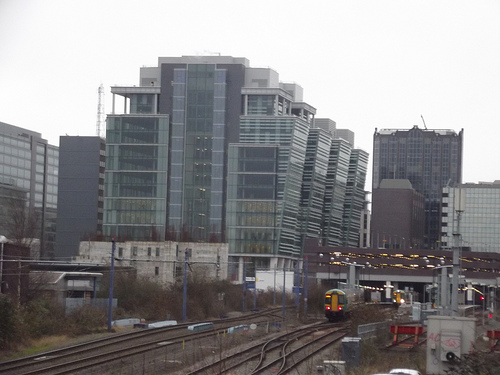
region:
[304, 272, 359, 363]
Yellow train on tracks.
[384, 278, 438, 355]
Yellow train on tracks.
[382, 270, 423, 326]
Headlights are on on the train.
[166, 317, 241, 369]
Many train tracks beside each other.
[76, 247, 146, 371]
Tall post in ground.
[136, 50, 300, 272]
Large building near tracks.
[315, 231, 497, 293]
Parking garage near trains.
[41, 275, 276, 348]
Brown trees near tracks.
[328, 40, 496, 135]
No clouds in the sky.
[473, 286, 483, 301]
Red light near tracks.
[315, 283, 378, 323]
a train on tracks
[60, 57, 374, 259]
large buildings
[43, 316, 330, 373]
railroad tracks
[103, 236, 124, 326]
a metal light pole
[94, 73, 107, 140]
a large antenna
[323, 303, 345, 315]
two red lights on a train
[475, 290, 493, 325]
rail road crossing lights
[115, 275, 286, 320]
bushes with green leaves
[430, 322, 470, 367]
an electric panel with warning sign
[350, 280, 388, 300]
rail road crossing bars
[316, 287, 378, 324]
grey and yellow train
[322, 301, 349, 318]
two red lights on train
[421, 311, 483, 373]
grey building with electric components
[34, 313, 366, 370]
train tracks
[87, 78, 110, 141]
large grey antenna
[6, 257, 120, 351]
large green bushes growing besides tracks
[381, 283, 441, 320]
train with two white lights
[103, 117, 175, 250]
building with large windows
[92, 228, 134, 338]
grey metal light pole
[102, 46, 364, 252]
a large building in the city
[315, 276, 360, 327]
a train on the railroad track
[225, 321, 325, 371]
railroad tracks in the city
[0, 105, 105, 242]
tall office buildings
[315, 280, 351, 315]
picture of a train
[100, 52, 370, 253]
building under construction in the city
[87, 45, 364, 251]
high rise office building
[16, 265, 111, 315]
work trailer in the bushes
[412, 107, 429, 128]
crane on the high rise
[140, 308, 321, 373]
multiple train tracks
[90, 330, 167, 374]
empty train tracks.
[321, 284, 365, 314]
train on the train tracks.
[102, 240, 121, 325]
pole alongside train tracks.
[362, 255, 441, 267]
lights inside parking structure.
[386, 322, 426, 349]
red sign near train tracks.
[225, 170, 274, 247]
glass windows on side of building.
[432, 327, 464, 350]
graffiti on side of structure.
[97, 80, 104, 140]
tower on top of building.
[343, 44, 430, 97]
gray sky above buildings.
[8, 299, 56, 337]
bushes next to train tracks.